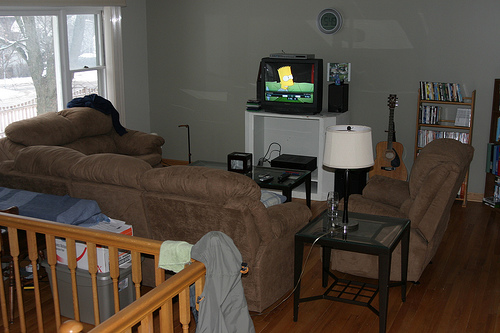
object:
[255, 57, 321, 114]
tv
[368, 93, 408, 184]
guitar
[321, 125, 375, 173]
lampshade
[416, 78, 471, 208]
shelf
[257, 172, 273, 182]
remote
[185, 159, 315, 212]
side table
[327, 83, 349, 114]
speaker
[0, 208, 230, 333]
crib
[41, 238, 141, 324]
container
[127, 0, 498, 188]
wall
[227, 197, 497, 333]
floor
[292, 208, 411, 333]
stand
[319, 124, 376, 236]
lamp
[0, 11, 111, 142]
screen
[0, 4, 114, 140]
window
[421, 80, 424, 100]
books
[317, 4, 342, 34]
clock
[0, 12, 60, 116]
tree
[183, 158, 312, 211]
table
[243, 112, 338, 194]
stand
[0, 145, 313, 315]
chairs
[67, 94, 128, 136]
clothes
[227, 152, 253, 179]
dvd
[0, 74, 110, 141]
snow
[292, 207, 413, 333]
side table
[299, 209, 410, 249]
glass